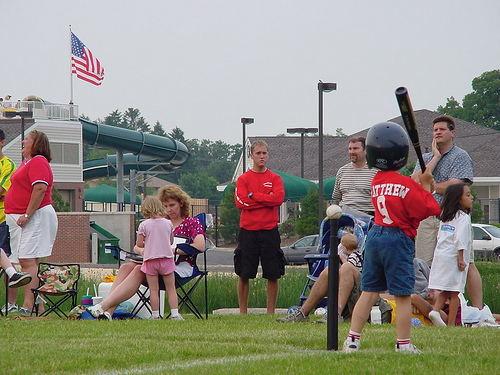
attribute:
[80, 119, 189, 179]
water slide — green, enclosed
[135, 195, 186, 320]
girl — little, wearing all pink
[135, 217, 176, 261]
shirt — white, pink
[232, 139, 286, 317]
boy — a teenager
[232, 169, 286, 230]
shirt — long sleeve, red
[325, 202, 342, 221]
baseball — white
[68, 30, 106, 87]
flag — american, waving, flying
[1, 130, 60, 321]
lady — laughing, laughing hard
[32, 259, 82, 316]
chair — camouflage, for child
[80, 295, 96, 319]
cup — reusable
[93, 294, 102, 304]
cup — reusable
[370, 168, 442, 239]
shirt — red, white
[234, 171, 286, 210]
arms — folded, crossed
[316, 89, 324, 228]
pole — black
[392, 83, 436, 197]
bat — black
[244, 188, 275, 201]
hands — folded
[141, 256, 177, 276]
shorts — pink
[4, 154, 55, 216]
shirt — pink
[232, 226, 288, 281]
shorts — black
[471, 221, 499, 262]
car — white, parked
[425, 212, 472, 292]
tee shirt — long, white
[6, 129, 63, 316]
woman — laughing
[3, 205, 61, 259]
shorts — white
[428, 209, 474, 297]
shirt — white, large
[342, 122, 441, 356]
boy — little, batting, playing t-ball